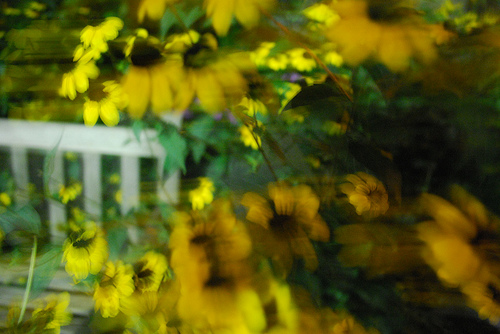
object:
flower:
[285, 46, 318, 73]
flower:
[57, 60, 101, 101]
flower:
[185, 174, 216, 210]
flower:
[338, 170, 391, 219]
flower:
[59, 217, 109, 281]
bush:
[0, 0, 497, 334]